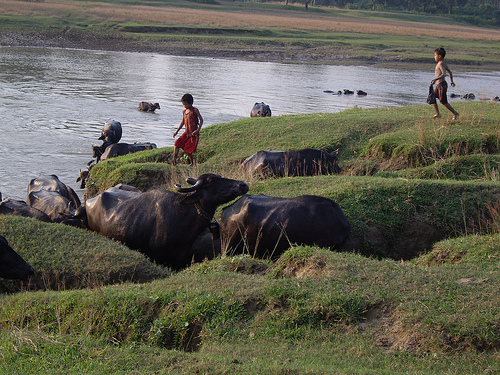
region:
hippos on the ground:
[39, 162, 338, 288]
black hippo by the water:
[19, 163, 87, 267]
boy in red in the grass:
[168, 80, 223, 172]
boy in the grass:
[412, 39, 471, 130]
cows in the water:
[295, 73, 377, 104]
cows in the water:
[126, 87, 166, 118]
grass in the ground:
[367, 132, 472, 299]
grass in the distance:
[112, 4, 394, 68]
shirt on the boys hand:
[415, 73, 437, 110]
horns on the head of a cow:
[159, 151, 274, 224]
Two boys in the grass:
[143, 40, 476, 158]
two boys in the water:
[135, 22, 474, 177]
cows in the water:
[84, 86, 283, 163]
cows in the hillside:
[3, 154, 392, 311]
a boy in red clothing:
[160, 90, 220, 162]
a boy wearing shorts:
[413, 30, 475, 126]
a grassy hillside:
[128, 115, 490, 330]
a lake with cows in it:
[5, 28, 440, 143]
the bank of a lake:
[13, 18, 359, 68]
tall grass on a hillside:
[382, 125, 499, 269]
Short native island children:
[170, 43, 468, 168]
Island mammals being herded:
[25, 100, 355, 265]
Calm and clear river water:
[0, 40, 497, 200]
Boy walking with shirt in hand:
[421, 45, 456, 120]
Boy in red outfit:
[170, 91, 200, 166]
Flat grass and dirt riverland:
[0, 0, 498, 70]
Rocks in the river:
[321, 85, 473, 95]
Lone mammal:
[135, 97, 160, 112]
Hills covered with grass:
[0, 100, 495, 370]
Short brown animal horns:
[170, 175, 200, 192]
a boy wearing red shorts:
[171, 95, 203, 165]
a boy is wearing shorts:
[425, 47, 461, 121]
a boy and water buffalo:
[8, 93, 351, 259]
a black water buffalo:
[83, 172, 249, 258]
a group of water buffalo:
[3, 171, 359, 298]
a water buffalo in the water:
[138, 101, 160, 116]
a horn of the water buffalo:
[175, 176, 202, 193]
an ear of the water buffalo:
[179, 191, 200, 210]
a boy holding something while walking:
[424, 46, 463, 121]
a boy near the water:
[171, 93, 204, 167]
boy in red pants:
[161, 128, 204, 158]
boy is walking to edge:
[422, 27, 457, 128]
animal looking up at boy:
[81, 168, 243, 233]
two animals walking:
[64, 175, 351, 258]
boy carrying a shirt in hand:
[417, 74, 434, 106]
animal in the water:
[128, 93, 164, 121]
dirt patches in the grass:
[321, 285, 414, 357]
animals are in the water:
[322, 72, 373, 98]